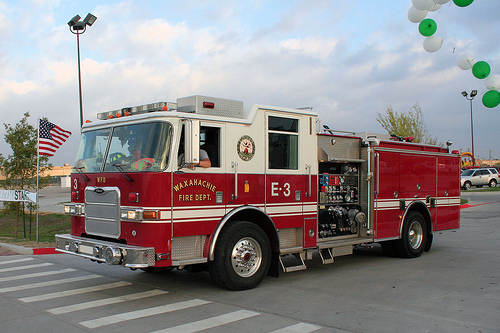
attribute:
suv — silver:
[479, 151, 484, 197]